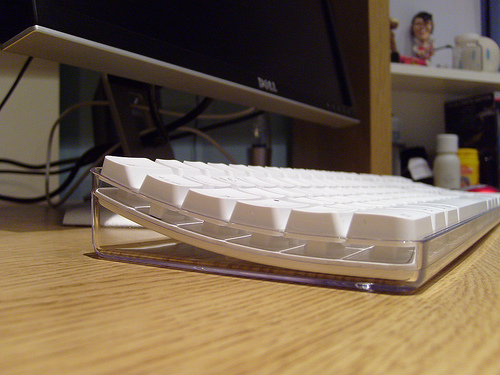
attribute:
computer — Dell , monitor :
[9, 2, 384, 124]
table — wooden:
[4, 184, 484, 371]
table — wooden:
[2, 197, 497, 374]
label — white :
[435, 162, 460, 188]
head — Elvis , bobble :
[399, 10, 444, 68]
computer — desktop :
[97, 154, 497, 290]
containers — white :
[429, 127, 483, 190]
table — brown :
[17, 235, 461, 365]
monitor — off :
[23, 19, 418, 147]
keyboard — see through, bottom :
[222, 165, 381, 253]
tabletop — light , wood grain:
[62, 245, 261, 362]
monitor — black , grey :
[0, 3, 368, 129]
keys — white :
[146, 151, 483, 253]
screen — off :
[0, 4, 443, 157]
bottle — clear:
[448, 26, 490, 76]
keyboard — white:
[90, 154, 486, 285]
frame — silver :
[137, 54, 330, 121]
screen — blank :
[274, 54, 342, 96]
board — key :
[113, 160, 498, 243]